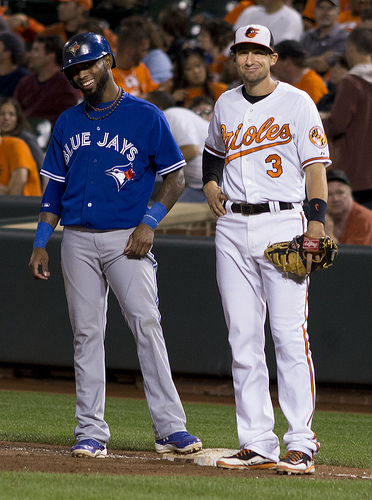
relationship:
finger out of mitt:
[305, 257, 314, 273] [272, 244, 303, 278]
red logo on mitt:
[302, 239, 320, 251] [272, 244, 303, 278]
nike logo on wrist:
[311, 200, 321, 214] [308, 221, 322, 229]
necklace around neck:
[86, 104, 116, 124] [101, 84, 115, 101]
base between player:
[200, 441, 217, 471] [201, 20, 328, 468]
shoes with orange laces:
[217, 448, 317, 475] [287, 452, 301, 462]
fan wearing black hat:
[327, 165, 371, 236] [329, 167, 349, 186]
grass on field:
[2, 395, 47, 441] [0, 371, 67, 497]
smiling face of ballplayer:
[80, 77, 101, 91] [30, 38, 207, 458]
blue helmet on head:
[93, 40, 105, 57] [58, 31, 119, 100]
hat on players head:
[230, 24, 273, 49] [58, 31, 119, 100]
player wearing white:
[201, 26, 332, 469] [286, 348, 299, 394]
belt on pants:
[219, 202, 285, 212] [212, 194, 307, 452]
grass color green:
[2, 395, 47, 441] [324, 426, 360, 453]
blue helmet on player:
[93, 40, 105, 57] [30, 38, 207, 458]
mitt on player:
[272, 244, 303, 278] [201, 26, 332, 469]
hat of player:
[230, 24, 273, 49] [201, 26, 332, 469]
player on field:
[201, 20, 328, 468] [0, 371, 67, 497]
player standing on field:
[201, 20, 328, 468] [0, 371, 67, 497]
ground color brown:
[121, 455, 149, 477] [26, 455, 51, 471]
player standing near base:
[201, 26, 332, 469] [200, 441, 217, 471]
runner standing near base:
[30, 38, 207, 458] [200, 441, 217, 471]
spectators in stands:
[124, 11, 222, 93] [0, 8, 39, 176]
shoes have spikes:
[217, 448, 317, 475] [278, 470, 308, 478]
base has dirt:
[200, 441, 217, 471] [204, 448, 220, 458]